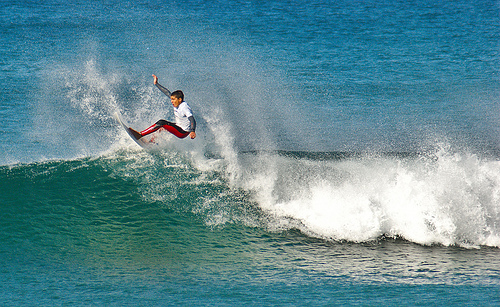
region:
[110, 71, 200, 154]
person riding a surfboard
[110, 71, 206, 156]
person riding a wave on a board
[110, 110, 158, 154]
white surboard in the water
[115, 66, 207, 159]
person wearing red and black pants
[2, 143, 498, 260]
small wave in the ocean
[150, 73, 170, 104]
arm of a person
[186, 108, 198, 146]
arm of a person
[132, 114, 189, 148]
pair of red and black pants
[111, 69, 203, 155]
person with black hair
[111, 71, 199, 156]
person wearing white shirt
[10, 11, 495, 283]
a surfer in the ocean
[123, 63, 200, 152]
right hand of surfer is in front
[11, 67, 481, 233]
a surfer on a wave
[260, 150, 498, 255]
water of wave is foamy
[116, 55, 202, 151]
surfer in bend backward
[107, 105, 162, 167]
surfboard is white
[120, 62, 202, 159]
surfer wears a tee shirt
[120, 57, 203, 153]
surfer wears wetsuit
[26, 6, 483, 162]
splashes of water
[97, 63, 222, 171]
surfer facing left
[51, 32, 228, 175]
a surfer jumping a wave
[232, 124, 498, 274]
waves crashing at the beach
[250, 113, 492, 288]
foamy ocean waves breaking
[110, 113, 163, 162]
a shiny white surf board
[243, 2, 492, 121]
beautiful blue ocean water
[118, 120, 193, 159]
red and black wet pants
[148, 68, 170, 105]
the arm of a surfer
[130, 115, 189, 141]
the leg of a surfer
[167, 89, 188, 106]
the head of a surfer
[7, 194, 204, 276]
ripples on the surface of the wave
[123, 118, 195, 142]
Black and red pants on surfer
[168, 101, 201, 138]
White shirt on surfer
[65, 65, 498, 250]
White sea waves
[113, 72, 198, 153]
Surfer riding against sea waves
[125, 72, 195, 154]
Surfer gliding on top of wave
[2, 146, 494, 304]
Large wave in ocean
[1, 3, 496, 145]
Deep blue ocean water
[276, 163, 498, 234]
Foaming splashing sea water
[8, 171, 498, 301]
Water ripples in the sea wave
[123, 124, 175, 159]
Surf board against the wave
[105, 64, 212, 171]
A man surfing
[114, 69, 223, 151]
a man on a surf board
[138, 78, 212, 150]
a man in a red and white wet suit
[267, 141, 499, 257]
white splash of the waves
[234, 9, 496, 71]
claim blue waters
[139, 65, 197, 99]
A arm of a surfer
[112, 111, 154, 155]
a white board of a surfer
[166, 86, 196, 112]
the head of a surfer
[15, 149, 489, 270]
A blue green wave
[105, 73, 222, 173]
a man with his arm in the air surfing